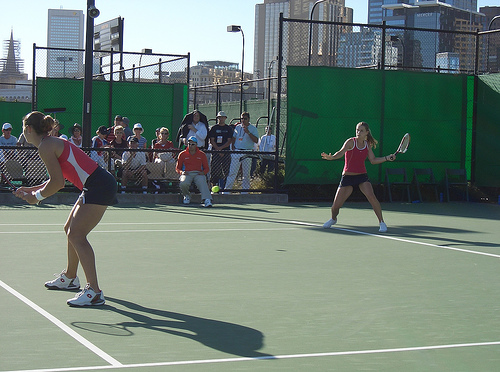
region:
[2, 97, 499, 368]
A tennis match is being played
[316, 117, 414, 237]
Woman holding a tennis racket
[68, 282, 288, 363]
A shadow on the court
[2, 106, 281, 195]
Spectators watching the game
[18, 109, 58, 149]
Brown hair in a bun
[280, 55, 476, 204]
A green wall in the background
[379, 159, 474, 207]
Three chairs in a row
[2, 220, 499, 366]
White lines on the court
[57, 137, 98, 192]
Red and white shirt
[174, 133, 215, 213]
An official sitting down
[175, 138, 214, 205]
a tennis coach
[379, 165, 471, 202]
row fo empty chairs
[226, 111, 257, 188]
spectator wearing all white and sunglasses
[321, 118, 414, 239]
tennis player ready to swing racket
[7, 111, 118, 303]
tennis player bending over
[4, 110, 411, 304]
a team of tennis players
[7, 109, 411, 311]
tennis players in red and black uniforms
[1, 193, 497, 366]
a green tennis court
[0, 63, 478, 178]
green mesh sun blocker on fence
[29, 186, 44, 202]
a white wristband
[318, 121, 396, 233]
girl playing tennis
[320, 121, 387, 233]
girl with a ponytail playing tennis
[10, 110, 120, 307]
girl with a bun is playing tennis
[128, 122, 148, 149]
a woman with a white hat in the audience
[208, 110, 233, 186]
man with a hat standing in the audience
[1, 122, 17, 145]
woman with white baseball cap in the audience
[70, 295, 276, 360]
a tennis player's and her racket's shadow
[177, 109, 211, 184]
a man standing in audience with his shirt over his head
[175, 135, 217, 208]
a coach wearing sunglasses sitting on the sidelines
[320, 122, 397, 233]
a tennis player with white shoes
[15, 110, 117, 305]
A lady playing tennis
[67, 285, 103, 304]
An athletic shoe worn on a lady's left foot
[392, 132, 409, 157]
A tennis racket in hand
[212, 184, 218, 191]
A green tennis ball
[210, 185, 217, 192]
A tennis ball in mid air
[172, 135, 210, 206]
A man wearing an orange pull-over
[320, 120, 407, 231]
A woman that just hit a tennis ball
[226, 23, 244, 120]
A light pole near a tennis court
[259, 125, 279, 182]
A man wearing a white shirt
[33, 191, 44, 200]
A wristband worn on a lady's left hand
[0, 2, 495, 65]
city buildings on horizon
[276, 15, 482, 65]
poles of chain link fence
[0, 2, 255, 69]
blue of daytime sky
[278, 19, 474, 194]
green cover on fence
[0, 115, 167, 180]
spectators seated behind fence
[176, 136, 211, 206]
seated man in red shirt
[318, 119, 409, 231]
tennis player with racket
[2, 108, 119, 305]
tennis player bent forward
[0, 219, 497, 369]
white lines on green court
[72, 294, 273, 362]
shadow of tennis player on court